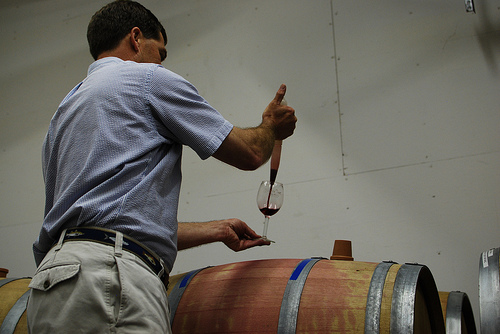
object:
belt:
[46, 220, 179, 294]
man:
[28, 17, 267, 328]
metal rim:
[392, 262, 447, 332]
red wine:
[253, 140, 289, 245]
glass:
[255, 178, 285, 245]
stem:
[257, 214, 266, 236]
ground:
[363, 199, 410, 236]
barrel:
[164, 239, 448, 334]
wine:
[259, 181, 280, 215]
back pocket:
[23, 264, 83, 329]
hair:
[83, 0, 168, 57]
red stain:
[173, 260, 354, 332]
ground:
[296, 27, 464, 111]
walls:
[7, 0, 499, 297]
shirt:
[36, 76, 236, 260]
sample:
[251, 167, 289, 215]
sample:
[257, 164, 280, 214]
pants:
[22, 224, 170, 332]